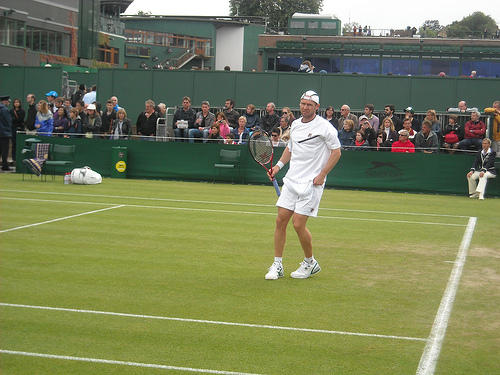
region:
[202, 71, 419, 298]
tennis player on court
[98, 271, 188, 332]
white line on court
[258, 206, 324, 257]
legs of the player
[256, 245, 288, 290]
white shoe on foot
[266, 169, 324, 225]
shorts on the player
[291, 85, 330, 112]
hat on the player's head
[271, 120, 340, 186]
white shirt on the player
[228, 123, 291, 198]
racket in man's hand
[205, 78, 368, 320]
This person is standing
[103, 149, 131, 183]
Yellow dot on the fence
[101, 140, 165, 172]
This fence is green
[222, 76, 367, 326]
One person on the court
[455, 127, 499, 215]
This person is sitting down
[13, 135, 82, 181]
A chair on the ground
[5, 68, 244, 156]
People in the stands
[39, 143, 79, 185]
Bench sitting on tennis court.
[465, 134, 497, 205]
Woman sitting on stool on tennis court.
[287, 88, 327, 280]
Tennis player wearing all white.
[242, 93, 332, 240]
Tennis player holding tennis racket.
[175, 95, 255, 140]
Men and women in crowd.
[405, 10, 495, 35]
Trees behind tennis courts.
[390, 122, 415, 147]
Man with red jacket on.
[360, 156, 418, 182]
Black writing on fence.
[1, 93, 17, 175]
Police officer talking to crowd.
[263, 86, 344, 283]
Man holding tennis racket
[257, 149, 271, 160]
Red letter M on tennis racket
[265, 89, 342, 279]
Man wearing white wristband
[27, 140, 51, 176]
Blanket on green chair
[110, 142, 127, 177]
Green trash can against green banner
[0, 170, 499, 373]
Tennis court is green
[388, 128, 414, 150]
Man wearing red sweater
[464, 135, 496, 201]
Woman is placing hands on knees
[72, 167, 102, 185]
White duffel bag next to green chair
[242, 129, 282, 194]
tennis racket in man's hand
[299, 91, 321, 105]
white scarf on man's head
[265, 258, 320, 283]
white tennis shoes on man's feet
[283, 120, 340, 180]
white t-shirt on man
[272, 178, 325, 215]
white shorts on man's legs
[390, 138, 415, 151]
red sweatshirt on man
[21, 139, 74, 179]
two green chairs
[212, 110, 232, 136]
lady in pink sweatshirt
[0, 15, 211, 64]
windows in buildings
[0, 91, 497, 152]
spectators watching tennis match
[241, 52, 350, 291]
a person in uniform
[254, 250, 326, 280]
the shoes are white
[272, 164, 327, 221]
the shorts are white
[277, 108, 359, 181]
the shirt is white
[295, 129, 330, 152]
a black line on shirt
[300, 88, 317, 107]
the hat is on backwards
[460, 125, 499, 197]
a man sitting down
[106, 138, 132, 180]
a green trashcan by banner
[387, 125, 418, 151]
a man wearing red shirt